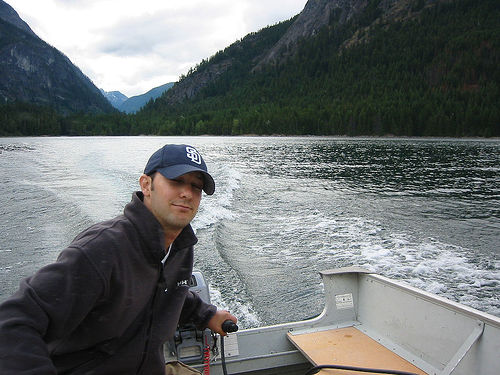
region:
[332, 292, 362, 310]
white electrical socket on boat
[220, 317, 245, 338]
man's hand on black object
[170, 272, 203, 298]
white label on man's jacket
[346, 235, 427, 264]
large white waves in water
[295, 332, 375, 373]
brown bench in boat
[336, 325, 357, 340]
small spot on brown bench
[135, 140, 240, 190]
man wearing dark blue cap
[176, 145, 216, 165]
white logo on blue cap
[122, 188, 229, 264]
collar of blue jacket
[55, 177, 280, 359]
man wearing large blue jacket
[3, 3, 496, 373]
the photo is clear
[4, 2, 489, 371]
the photo was taken outside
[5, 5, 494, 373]
the photo was taken during the day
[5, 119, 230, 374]
a person is in the photo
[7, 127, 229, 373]
the person is a man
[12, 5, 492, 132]
trees are in the photo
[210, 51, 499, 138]
the trees are green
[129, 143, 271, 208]
the man has a cap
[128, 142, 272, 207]
the cap is blue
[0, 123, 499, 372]
the man is riding ina boat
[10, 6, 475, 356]
a man enjoying a boat ride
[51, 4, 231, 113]
a valley between moutains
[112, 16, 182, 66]
white clouds in the sky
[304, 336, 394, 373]
a wooden bench on a boat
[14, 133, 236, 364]
a man wearing a blue cap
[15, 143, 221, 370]
a man wearing a blue jacket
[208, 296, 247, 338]
a hand gripping a handle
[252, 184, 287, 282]
ripples made by the boat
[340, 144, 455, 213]
a calm lake of dark green water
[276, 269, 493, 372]
a boat racing along a lake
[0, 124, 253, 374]
Man is in a boat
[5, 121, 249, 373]
Man wears blue cap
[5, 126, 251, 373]
Man holds a handle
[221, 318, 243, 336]
Handle is black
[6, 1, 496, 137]
Mountains behind a body of water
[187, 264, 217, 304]
Engine of boat is tan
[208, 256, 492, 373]
Boat is white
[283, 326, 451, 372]
Boat has brown sits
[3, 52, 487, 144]
Green trees in the background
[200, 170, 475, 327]
Choppy waters formed with the passage of boat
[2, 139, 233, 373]
man wearing blue hat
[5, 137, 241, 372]
man driving a boat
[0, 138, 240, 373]
man wearing grey sweater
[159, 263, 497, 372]
boat floating in water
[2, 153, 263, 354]
waves in the water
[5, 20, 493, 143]
trees along the mountain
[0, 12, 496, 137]
trees are green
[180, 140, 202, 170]
white logo on blue hat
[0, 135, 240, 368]
man is smilng for a picture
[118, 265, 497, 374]
boat has wooden bench